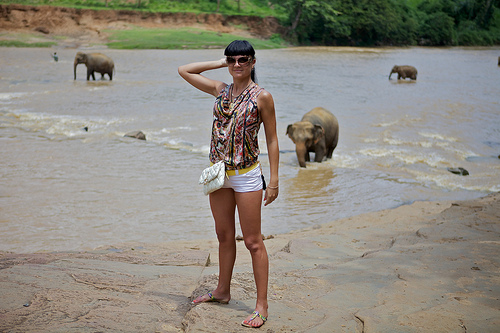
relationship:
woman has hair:
[184, 39, 281, 330] [224, 35, 257, 86]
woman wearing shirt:
[184, 39, 281, 330] [213, 79, 258, 164]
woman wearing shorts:
[184, 39, 281, 330] [210, 171, 265, 192]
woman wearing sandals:
[184, 39, 281, 330] [200, 292, 269, 331]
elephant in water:
[287, 105, 335, 167] [2, 48, 500, 154]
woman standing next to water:
[184, 39, 281, 330] [2, 48, 500, 154]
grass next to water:
[115, 31, 205, 52] [2, 48, 500, 154]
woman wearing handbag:
[184, 39, 281, 330] [199, 153, 232, 192]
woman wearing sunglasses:
[184, 39, 281, 330] [226, 52, 246, 62]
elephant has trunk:
[287, 105, 335, 167] [294, 141, 308, 168]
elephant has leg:
[287, 105, 335, 167] [314, 146, 327, 165]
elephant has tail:
[67, 49, 123, 83] [110, 60, 117, 75]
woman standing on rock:
[184, 39, 281, 330] [199, 274, 285, 333]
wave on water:
[4, 81, 103, 137] [2, 48, 500, 154]